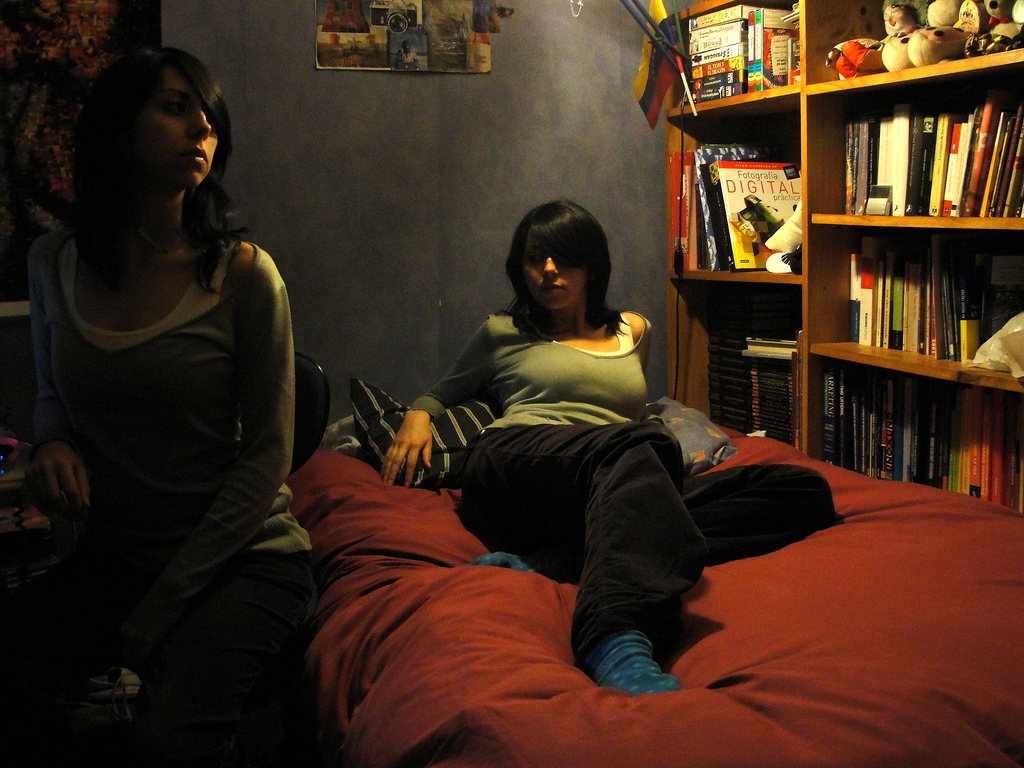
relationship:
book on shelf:
[724, 160, 805, 274] [668, 103, 805, 274]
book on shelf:
[675, 279, 809, 436] [677, 379, 817, 457]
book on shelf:
[671, 150, 858, 261] [663, 261, 820, 295]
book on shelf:
[662, 164, 704, 276] [662, 244, 810, 293]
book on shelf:
[837, 125, 857, 224] [797, 194, 1020, 246]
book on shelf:
[846, 119, 870, 206] [797, 204, 1020, 250]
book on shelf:
[924, 112, 981, 189] [796, 203, 1022, 243]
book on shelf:
[867, 230, 877, 344] [797, 332, 1021, 402]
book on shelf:
[818, 340, 839, 461] [796, 414, 1020, 509]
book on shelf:
[858, 115, 928, 259] [794, 204, 1021, 236]